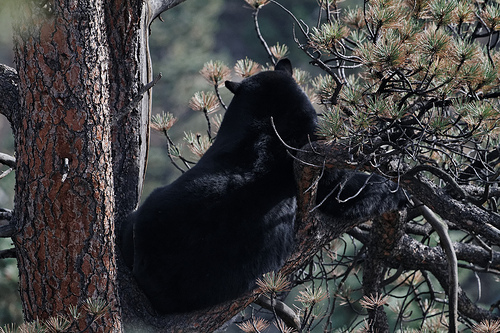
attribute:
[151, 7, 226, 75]
trees — back ground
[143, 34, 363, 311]
cat — back 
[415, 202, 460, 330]
limb — brown, small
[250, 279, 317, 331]
limb — brown, small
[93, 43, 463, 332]
bear — black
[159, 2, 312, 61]
trees — blurred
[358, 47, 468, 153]
needles — small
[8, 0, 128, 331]
trunk — large, brown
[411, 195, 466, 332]
limb — small, brown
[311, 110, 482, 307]
tree — brown, small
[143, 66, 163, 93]
limb — small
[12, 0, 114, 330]
trunk — pine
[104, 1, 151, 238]
trunk — pine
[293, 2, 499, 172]
leaves — green, brown